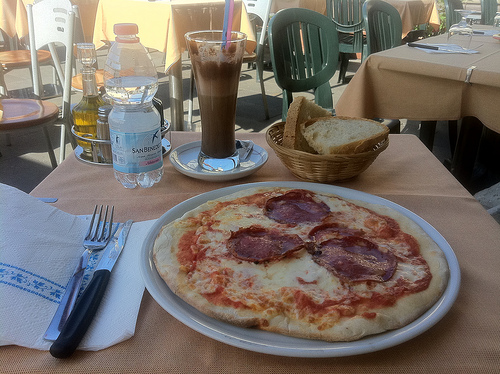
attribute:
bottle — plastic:
[104, 18, 166, 191]